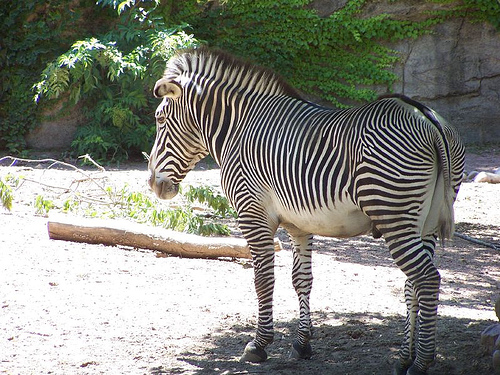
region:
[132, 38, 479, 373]
A single zebra standing still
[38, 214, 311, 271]
A log laying on the ground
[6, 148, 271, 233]
A leafy branch on the ground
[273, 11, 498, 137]
A stone wall in the background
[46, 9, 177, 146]
A small tree near the wall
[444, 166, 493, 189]
A small collection of rocks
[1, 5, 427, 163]
Leafy vines growing along the rock wall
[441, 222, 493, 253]
Another stick on the ground behind the zebra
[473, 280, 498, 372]
Some more rocks near the zebra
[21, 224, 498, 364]
Dirt ground the zebra is standing on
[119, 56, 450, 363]
a zebra standing alone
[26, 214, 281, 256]
a tree limb on the ground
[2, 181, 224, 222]
a tree limb with leaves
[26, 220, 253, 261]
a wood log on the ground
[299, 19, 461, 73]
vines growing on a rock wall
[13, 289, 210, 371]
gravel on the ground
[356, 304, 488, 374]
a shadow on the ground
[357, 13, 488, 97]
a rock wall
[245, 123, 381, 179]
stripes on a zebra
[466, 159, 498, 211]
rocks on the ground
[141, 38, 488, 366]
One zebra is visible.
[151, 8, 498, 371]
Most of the zebra is in the shade.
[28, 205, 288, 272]
A log on the ground.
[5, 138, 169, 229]
Twig on the ground.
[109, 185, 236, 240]
Leaves on the twig.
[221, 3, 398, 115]
Plant growing on the rock.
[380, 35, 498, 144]
The rock is grey.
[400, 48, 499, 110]
Cracks in the rock.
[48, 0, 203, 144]
The leaves are green.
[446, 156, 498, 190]
Rocks in the background.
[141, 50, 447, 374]
A black and white zebra.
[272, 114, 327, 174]
Part of the black stripes.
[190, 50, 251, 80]
Part of the black and white mane.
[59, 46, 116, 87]
Part of the green leafy tree.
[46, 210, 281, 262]
A long brown log.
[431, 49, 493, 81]
Part of the stone wall.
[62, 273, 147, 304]
Part of the ground.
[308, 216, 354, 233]
Part of the zebra's white belly.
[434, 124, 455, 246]
The zebra's tail.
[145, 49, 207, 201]
The head of the zebra.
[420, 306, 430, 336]
part of a zebra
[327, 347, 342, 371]
part of a shadow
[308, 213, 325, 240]
part of a zebra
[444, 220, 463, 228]
part of a tail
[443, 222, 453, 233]
edge of a tail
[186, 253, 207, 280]
edge of a log